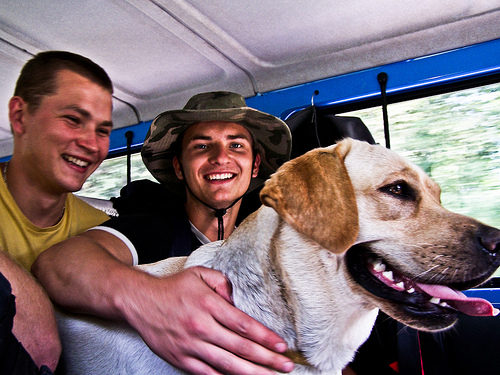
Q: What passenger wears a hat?
A: The one in the center.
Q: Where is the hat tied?
A: Under the chin.